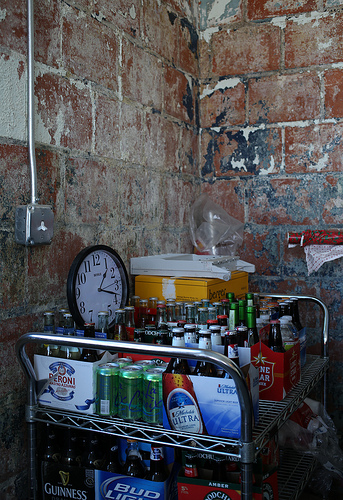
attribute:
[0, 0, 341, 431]
wall — part, brick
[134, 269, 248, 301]
yellow box — yellow color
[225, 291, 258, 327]
bottles — green colored, five, green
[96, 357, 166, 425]
cans — Green 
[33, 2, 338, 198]
wall — red 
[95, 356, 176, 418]
cans — six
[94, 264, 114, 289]
hand — small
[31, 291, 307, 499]
beer — different, brands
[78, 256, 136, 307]
hands — Black 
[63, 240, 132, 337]
clock — round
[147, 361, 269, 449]
beer — cases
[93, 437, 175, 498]
pack — twelve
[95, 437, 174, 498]
bud beer — Bud Light